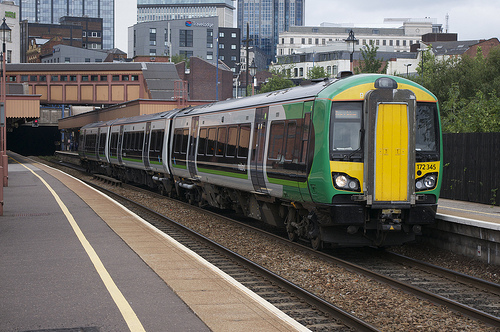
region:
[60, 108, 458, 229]
green and yellow train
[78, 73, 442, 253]
train is green white and yellow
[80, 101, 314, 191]
the windows on train are tinted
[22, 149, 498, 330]
black tracks under train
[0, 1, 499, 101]
large buildings in background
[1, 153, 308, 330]
train platform is black with yellow line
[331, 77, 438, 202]
five lights on front of train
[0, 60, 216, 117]
large covered bridge over tracks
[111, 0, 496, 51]
sky is blue behind buildings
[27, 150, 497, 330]
gravel beside train tracks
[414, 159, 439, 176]
number on train face is 172345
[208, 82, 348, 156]
a train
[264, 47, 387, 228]
a train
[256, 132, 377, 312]
a train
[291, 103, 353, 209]
a train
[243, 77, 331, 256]
a train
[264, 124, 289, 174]
a train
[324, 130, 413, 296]
a train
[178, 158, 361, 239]
train is yellow and green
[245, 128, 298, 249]
train is yellow and green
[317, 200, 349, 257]
train is yellow and green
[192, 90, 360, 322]
train is yellow and green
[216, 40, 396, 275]
train is yellow and green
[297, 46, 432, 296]
train is yellow and green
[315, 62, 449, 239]
front of train looks like a face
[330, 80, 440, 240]
long yellow door is nose, slanted headlights are eyes, bottom of door is mouth where license plate would be is teeth or chin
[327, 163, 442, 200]
headlights have an artistically wavy slant, unusual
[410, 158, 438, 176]
train is '172345'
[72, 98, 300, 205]
many doors line the train's side, evenly spaced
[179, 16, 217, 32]
red+blue logo w/ white text @ top of grey building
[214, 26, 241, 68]
six almost perfectly square windows on a dark grey building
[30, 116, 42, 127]
red light! stoplight in tunnel for train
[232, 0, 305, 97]
tall+many windowed skyscraper in far distance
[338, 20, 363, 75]
old fashioned, victorianesque type street lamp, black w/ elaborate pointy shade, middle distance, right